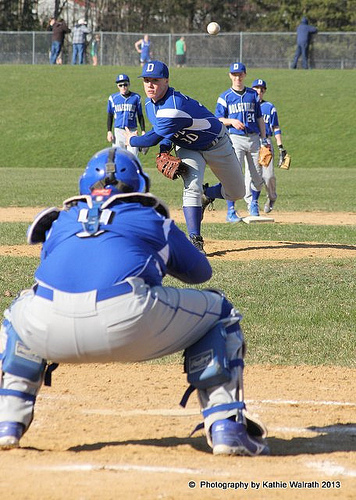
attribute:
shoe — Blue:
[211, 419, 270, 456]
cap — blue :
[230, 62, 237, 75]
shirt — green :
[172, 41, 187, 56]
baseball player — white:
[213, 62, 272, 223]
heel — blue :
[191, 415, 258, 460]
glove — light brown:
[152, 150, 185, 181]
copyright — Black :
[185, 477, 343, 491]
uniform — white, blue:
[102, 63, 149, 191]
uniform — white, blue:
[211, 56, 268, 227]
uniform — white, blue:
[244, 73, 290, 216]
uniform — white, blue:
[124, 50, 248, 264]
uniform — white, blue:
[0, 146, 287, 460]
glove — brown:
[155, 147, 181, 185]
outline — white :
[242, 389, 330, 465]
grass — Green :
[260, 267, 344, 325]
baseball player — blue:
[209, 59, 270, 143]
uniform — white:
[218, 87, 260, 137]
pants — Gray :
[0, 277, 247, 446]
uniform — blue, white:
[106, 92, 144, 157]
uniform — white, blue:
[131, 96, 248, 206]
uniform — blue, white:
[214, 88, 267, 198]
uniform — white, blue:
[256, 97, 285, 192]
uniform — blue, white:
[11, 186, 250, 442]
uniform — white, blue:
[101, 89, 145, 156]